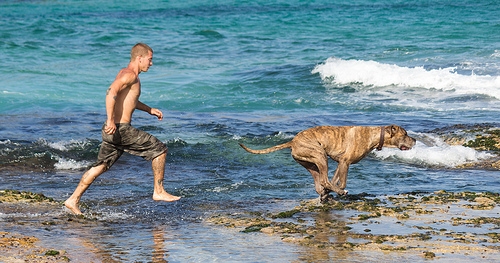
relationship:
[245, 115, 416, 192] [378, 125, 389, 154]
dog with collar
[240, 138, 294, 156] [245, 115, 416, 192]
tail of dog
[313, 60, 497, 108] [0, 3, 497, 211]
wave in ocean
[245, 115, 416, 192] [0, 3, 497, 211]
dog in ocean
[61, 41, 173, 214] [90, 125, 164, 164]
man wearing shorts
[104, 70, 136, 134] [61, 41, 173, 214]
arm of man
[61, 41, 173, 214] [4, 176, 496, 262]
man on top of shore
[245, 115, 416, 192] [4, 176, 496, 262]
dog in shore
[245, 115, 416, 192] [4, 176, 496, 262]
dog on top of shore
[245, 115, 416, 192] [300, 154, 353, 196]
dog has legs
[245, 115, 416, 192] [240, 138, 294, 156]
dog has tail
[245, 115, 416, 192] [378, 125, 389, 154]
dog has collar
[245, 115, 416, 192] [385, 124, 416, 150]
dog has head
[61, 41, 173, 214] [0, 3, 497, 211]
man in ocean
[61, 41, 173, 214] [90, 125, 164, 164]
man has shorts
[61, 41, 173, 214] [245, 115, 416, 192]
man chasing dog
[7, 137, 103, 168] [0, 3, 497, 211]
rocks in ocean